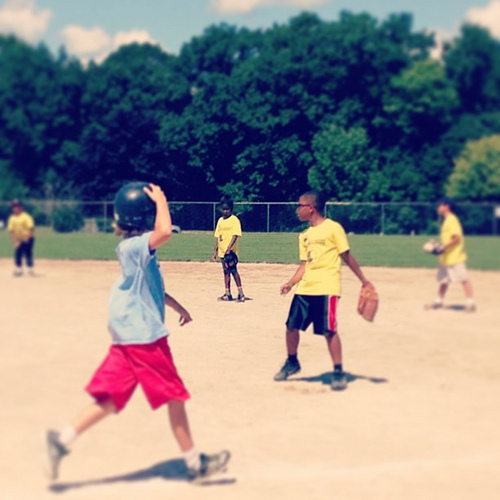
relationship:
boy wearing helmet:
[42, 171, 231, 483] [112, 177, 172, 243]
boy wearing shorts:
[270, 186, 381, 392] [287, 289, 343, 338]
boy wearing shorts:
[42, 171, 231, 483] [85, 330, 199, 420]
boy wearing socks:
[42, 171, 252, 487] [175, 443, 212, 479]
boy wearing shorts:
[209, 196, 252, 311] [219, 246, 246, 278]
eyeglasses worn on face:
[294, 201, 312, 208] [293, 191, 307, 222]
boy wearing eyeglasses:
[270, 186, 381, 392] [294, 201, 312, 208]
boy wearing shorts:
[421, 199, 479, 314] [435, 260, 468, 285]